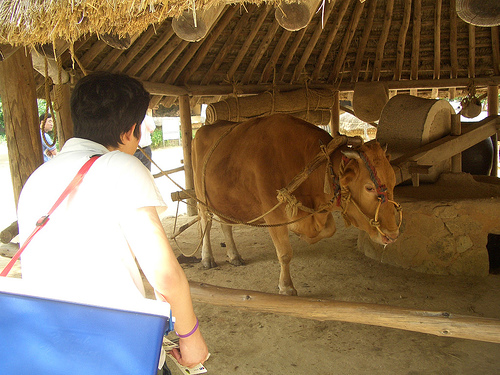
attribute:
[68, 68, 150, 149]
hair — black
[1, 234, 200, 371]
bag — white, blue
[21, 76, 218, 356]
shirt — white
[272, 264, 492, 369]
pole — wooden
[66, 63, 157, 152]
hair — dark brown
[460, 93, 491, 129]
bag — blue, white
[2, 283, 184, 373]
bag — blue, white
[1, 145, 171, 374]
bag — white, blue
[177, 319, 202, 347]
band — purple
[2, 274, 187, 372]
bag — blue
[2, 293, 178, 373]
kit — blue